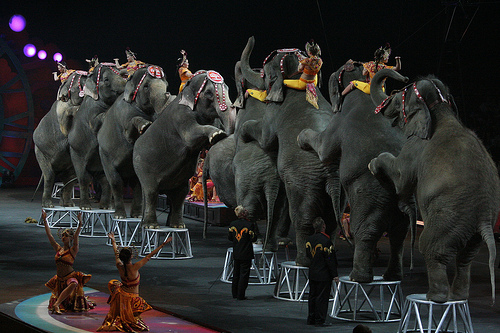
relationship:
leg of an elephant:
[418, 225, 455, 305] [358, 73, 497, 303]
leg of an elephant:
[103, 166, 127, 212] [299, 55, 409, 285]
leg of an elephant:
[103, 166, 127, 212] [132, 67, 233, 229]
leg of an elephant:
[103, 167, 131, 221] [97, 60, 172, 212]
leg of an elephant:
[34, 157, 59, 207] [31, 62, 91, 206]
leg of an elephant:
[424, 261, 451, 294] [358, 73, 497, 303]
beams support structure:
[336, 284, 354, 317] [330, 275, 405, 323]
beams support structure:
[359, 286, 381, 321] [330, 275, 405, 323]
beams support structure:
[384, 286, 399, 318] [330, 275, 405, 323]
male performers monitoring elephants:
[221, 205, 340, 323] [29, 54, 499, 261]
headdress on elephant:
[199, 65, 229, 114] [365, 67, 492, 232]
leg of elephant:
[103, 166, 127, 212] [66, 60, 135, 207]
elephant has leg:
[366, 64, 500, 305] [75, 167, 90, 201]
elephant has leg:
[73, 59, 123, 216] [67, 177, 97, 210]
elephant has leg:
[366, 64, 500, 305] [109, 157, 204, 230]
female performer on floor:
[103, 229, 172, 329] [0, 179, 496, 328]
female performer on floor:
[38, 209, 94, 317] [0, 179, 496, 328]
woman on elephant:
[286, 40, 323, 102] [358, 73, 497, 303]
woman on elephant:
[337, 42, 399, 90] [239, 29, 336, 259]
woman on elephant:
[168, 47, 193, 94] [133, 66, 227, 218]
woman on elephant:
[286, 40, 323, 102] [133, 66, 227, 218]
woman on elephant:
[110, 46, 140, 81] [97, 60, 172, 212]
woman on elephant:
[51, 55, 68, 77] [32, 63, 89, 220]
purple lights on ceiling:
[6, 5, 73, 72] [2, 3, 498, 40]